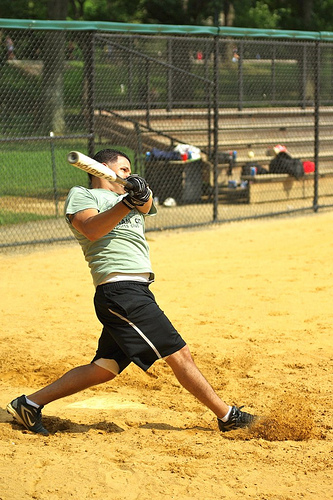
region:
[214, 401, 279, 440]
base ball cleats kicking dirt in the air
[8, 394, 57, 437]
bike brand base ball cleats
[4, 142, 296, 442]
a man swinging a base ball bat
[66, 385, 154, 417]
white home base covered with dirt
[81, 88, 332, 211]
metal base ball bleacher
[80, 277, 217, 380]
black shorts a man is wearing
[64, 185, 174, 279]
green shirt on a man's back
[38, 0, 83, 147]
tree in the background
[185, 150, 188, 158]
red plastic cup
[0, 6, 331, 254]
black chain link fence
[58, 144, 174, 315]
man holding a bat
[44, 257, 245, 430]
the shorts are black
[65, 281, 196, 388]
the shorts are black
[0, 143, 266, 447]
man swinging base ball bat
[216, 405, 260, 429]
black cleat on man's foot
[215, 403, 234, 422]
white sock on ankle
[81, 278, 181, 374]
black and white shorts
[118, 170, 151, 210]
black baseball gloves on hands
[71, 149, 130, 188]
white and black base ball bat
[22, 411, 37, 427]
nike logo on cleats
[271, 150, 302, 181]
black bag sitting on bleachers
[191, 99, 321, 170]
metal stands by field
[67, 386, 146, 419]
home plate covered by dirt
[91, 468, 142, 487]
shoe print in the dirt.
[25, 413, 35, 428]
logo on the shoe.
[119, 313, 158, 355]
stripe on man's shorts.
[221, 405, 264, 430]
shoe on man's foot.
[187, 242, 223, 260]
dirt on the ground.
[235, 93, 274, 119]
fence near the bleachers.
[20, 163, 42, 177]
grass on the ground.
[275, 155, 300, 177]
bag on the bleachers.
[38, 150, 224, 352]
a person playing baseball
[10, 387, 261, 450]
he is using proper form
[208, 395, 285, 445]
his front foot is digging into the dirt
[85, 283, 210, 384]
he has on black shorts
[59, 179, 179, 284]
he is wearing a green shirt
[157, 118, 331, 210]
items on the bleachers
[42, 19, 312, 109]
the field's fence has a green top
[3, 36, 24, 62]
a person in the distance